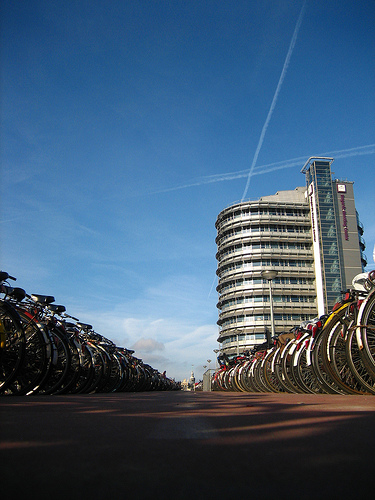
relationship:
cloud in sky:
[0, 0, 375, 385] [10, 31, 69, 99]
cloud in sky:
[0, 0, 375, 385] [0, 0, 372, 388]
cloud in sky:
[0, 0, 375, 385] [75, 68, 210, 168]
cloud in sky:
[0, 0, 375, 385] [37, 45, 217, 147]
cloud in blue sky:
[125, 312, 246, 363] [0, 0, 375, 384]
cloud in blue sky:
[0, 0, 375, 385] [3, 4, 364, 154]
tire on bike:
[277, 346, 314, 406] [256, 320, 304, 400]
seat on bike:
[29, 287, 56, 306] [0, 290, 60, 395]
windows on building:
[213, 207, 310, 218] [214, 156, 369, 361]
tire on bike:
[6, 316, 169, 399] [189, 278, 373, 387]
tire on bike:
[356, 286, 373, 382] [318, 287, 373, 393]